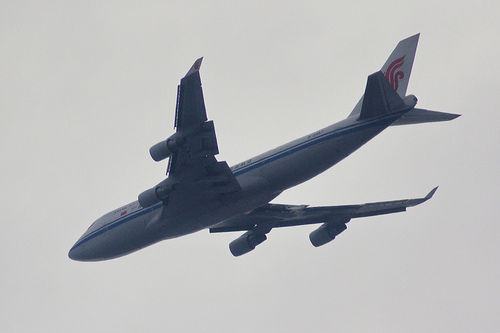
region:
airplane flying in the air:
[45, 2, 499, 299]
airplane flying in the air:
[40, 18, 498, 293]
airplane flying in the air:
[37, 3, 485, 287]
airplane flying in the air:
[53, 19, 463, 331]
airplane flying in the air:
[25, 23, 496, 303]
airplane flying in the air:
[39, 22, 479, 290]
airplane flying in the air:
[57, 11, 472, 288]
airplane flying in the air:
[40, 13, 480, 311]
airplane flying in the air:
[39, 13, 476, 300]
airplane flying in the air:
[47, 13, 471, 284]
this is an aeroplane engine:
[146, 128, 181, 163]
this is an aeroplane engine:
[228, 229, 263, 263]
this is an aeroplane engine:
[303, 220, 340, 253]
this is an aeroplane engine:
[132, 183, 173, 207]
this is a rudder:
[386, 30, 420, 84]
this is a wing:
[171, 52, 221, 170]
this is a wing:
[270, 180, 453, 245]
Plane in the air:
[54, 27, 469, 280]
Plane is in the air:
[57, 24, 467, 279]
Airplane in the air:
[53, 24, 468, 272]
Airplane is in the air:
[53, 25, 470, 271]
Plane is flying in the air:
[55, 25, 472, 282]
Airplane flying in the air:
[55, 22, 464, 268]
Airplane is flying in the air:
[60, 22, 472, 274]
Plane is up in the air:
[59, 22, 462, 272]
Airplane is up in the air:
[45, 25, 469, 284]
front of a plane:
[60, 204, 118, 289]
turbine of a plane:
[123, 170, 175, 213]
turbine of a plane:
[130, 132, 181, 170]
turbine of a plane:
[214, 227, 266, 267]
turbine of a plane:
[305, 225, 333, 244]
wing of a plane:
[145, 34, 232, 189]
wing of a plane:
[258, 165, 454, 250]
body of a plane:
[150, 120, 305, 270]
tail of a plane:
[302, 58, 453, 158]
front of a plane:
[60, 204, 135, 274]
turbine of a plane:
[146, 118, 206, 161]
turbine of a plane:
[129, 168, 187, 209]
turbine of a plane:
[228, 215, 281, 256]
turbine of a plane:
[288, 200, 384, 267]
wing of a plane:
[126, 53, 233, 196]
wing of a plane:
[302, 174, 459, 244]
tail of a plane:
[340, 30, 460, 150]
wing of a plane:
[405, 90, 468, 141]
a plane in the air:
[35, 23, 415, 322]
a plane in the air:
[62, 25, 493, 281]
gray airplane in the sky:
[52, 34, 473, 284]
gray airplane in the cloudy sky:
[58, 27, 477, 295]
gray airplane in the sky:
[37, 18, 452, 290]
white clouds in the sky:
[354, 250, 461, 307]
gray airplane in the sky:
[43, 40, 445, 302]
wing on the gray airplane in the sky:
[139, 33, 249, 199]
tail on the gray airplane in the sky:
[332, 36, 472, 143]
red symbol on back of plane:
[380, 40, 409, 103]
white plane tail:
[370, 34, 457, 147]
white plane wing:
[217, 191, 435, 253]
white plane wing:
[150, 57, 243, 194]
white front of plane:
[62, 209, 111, 267]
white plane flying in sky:
[72, 37, 459, 306]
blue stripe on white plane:
[67, 105, 409, 245]